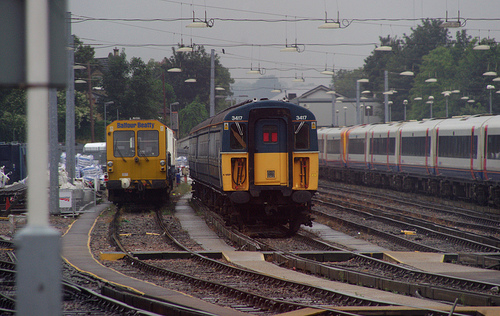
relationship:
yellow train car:
[105, 119, 176, 179] [103, 119, 176, 206]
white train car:
[319, 116, 500, 181] [103, 119, 176, 206]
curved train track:
[105, 232, 282, 305] [106, 214, 498, 316]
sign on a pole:
[0, 0, 80, 87] [14, 87, 63, 293]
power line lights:
[73, 0, 498, 102] [186, 20, 212, 30]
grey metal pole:
[15, 229, 62, 316] [14, 87, 63, 293]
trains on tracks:
[175, 97, 320, 232] [106, 214, 498, 316]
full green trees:
[2, 28, 232, 143] [2, 17, 499, 144]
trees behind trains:
[2, 17, 499, 144] [175, 97, 320, 232]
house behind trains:
[292, 89, 385, 127] [175, 97, 320, 232]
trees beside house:
[2, 17, 499, 144] [292, 89, 385, 127]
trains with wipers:
[175, 97, 320, 232] [113, 142, 152, 163]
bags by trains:
[58, 150, 106, 186] [175, 97, 320, 232]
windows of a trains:
[137, 130, 160, 142] [175, 97, 320, 232]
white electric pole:
[319, 116, 500, 181] [14, 87, 63, 293]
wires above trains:
[71, 14, 493, 26] [175, 97, 320, 232]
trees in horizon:
[2, 17, 499, 144] [73, 0, 498, 102]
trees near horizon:
[2, 17, 499, 144] [73, 0, 498, 102]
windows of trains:
[137, 130, 160, 142] [175, 97, 320, 232]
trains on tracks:
[106, 97, 499, 230] [106, 214, 498, 316]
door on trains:
[253, 118, 288, 189] [175, 97, 320, 232]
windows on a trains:
[113, 130, 160, 156] [175, 97, 320, 232]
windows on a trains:
[137, 130, 160, 142] [175, 97, 320, 232]